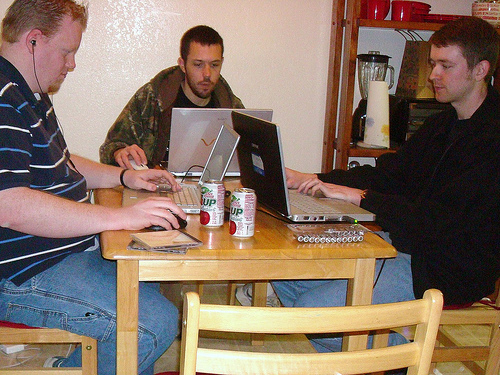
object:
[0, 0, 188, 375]
man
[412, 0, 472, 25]
dishes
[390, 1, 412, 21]
dishes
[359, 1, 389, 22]
dishes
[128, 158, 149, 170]
mouse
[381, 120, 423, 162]
ground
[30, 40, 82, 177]
ear bud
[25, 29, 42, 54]
ear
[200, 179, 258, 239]
sodas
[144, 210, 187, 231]
mouse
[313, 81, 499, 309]
coat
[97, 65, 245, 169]
coat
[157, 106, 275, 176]
computer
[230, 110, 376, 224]
computer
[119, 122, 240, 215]
computer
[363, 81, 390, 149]
paper towels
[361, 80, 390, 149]
cup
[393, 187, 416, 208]
ground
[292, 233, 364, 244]
batteries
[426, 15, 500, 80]
short hair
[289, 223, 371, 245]
package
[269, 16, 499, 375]
man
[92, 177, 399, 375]
table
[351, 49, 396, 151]
blender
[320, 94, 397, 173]
shelf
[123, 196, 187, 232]
hand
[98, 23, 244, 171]
man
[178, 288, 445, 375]
chair